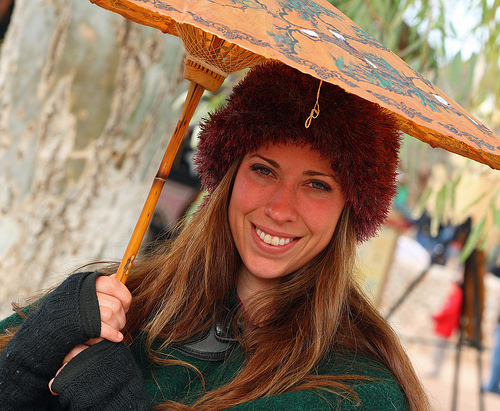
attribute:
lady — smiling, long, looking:
[7, 72, 434, 409]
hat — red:
[189, 59, 398, 238]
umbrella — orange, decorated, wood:
[6, 0, 497, 278]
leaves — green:
[337, 2, 499, 137]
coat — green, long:
[3, 261, 411, 409]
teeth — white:
[255, 225, 293, 247]